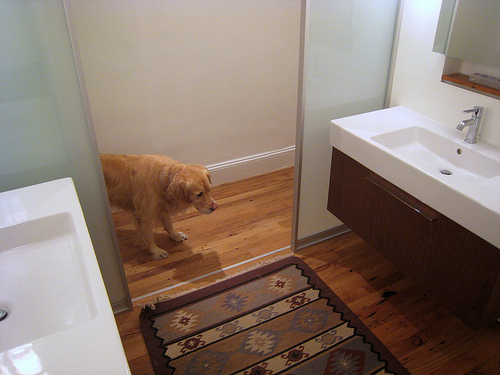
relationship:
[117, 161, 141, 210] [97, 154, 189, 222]
jersey on body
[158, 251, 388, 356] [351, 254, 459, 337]
rug on floor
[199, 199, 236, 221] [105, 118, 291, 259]
nose on dog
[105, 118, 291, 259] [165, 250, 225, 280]
dog has shadow